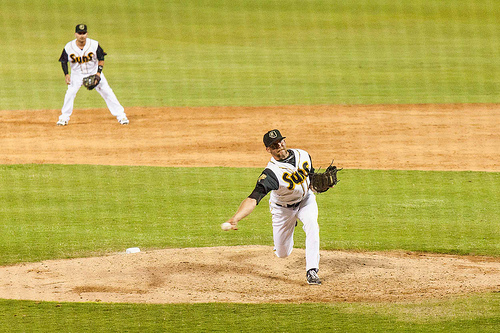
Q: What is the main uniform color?
A: White.